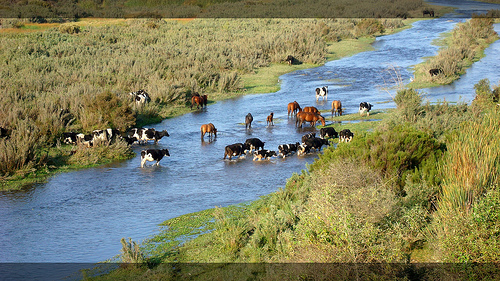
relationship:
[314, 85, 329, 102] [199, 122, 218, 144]
animal and horse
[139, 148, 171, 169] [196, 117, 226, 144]
animal and horse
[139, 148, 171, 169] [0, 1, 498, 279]
animal in a river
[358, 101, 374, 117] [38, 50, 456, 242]
animal standing in water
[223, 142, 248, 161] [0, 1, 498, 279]
animal crossing river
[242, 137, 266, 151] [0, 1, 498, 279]
cow crossing river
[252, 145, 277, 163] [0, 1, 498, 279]
cows crossing river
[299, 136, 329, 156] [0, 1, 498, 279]
cows crossing river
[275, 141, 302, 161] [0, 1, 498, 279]
cows crossing river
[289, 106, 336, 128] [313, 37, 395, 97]
horse drinking water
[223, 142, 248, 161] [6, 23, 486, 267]
animal walking through water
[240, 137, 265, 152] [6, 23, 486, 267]
cow walking through water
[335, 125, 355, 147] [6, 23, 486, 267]
cow walking through water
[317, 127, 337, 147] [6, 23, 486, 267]
cow walking through water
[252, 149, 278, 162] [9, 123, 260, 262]
cows crossing river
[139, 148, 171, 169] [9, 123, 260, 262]
animal crossing river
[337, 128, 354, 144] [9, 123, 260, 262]
cow crossing river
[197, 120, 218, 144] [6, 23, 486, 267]
horse standing in water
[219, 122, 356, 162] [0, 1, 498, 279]
group crossing river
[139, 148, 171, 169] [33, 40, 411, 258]
animal standing in water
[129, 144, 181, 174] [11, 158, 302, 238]
animal standing in water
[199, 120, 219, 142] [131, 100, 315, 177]
animal standing in water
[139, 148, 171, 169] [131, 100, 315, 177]
animal standing in water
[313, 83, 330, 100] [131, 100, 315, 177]
animal standing in water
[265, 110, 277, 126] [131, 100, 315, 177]
animal standing in water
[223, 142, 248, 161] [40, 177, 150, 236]
animal standing in water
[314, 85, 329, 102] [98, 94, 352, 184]
animal standing in water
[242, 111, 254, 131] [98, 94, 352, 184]
animal standing in water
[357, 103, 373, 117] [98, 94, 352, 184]
animal standing in water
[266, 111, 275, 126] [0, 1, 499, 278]
animal standing in water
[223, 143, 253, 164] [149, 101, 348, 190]
animal standing in water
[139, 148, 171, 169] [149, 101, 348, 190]
animal standing in water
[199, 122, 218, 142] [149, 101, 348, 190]
animal standing in water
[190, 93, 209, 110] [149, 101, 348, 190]
animal standing in water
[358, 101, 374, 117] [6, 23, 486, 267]
animal standing in water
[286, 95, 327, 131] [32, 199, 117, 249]
horses in water